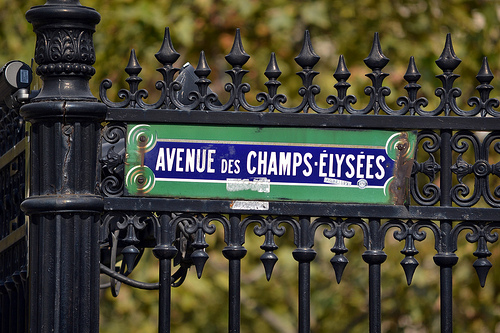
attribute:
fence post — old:
[18, 0, 108, 330]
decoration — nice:
[33, 25, 95, 79]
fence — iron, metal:
[2, 3, 499, 330]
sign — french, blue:
[147, 137, 397, 189]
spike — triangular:
[436, 37, 469, 80]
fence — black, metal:
[32, 37, 485, 272]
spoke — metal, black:
[435, 31, 457, 331]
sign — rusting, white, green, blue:
[129, 119, 420, 216]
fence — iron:
[16, 16, 487, 308]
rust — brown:
[393, 135, 415, 212]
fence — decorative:
[142, 13, 262, 328]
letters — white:
[154, 146, 385, 179]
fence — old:
[113, 29, 240, 329]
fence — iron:
[29, 35, 499, 309]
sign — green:
[79, 121, 415, 202]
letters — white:
[154, 142, 386, 182]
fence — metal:
[36, 219, 347, 319]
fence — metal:
[94, 215, 332, 295]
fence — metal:
[70, 227, 445, 312]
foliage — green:
[192, 18, 355, 62]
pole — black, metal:
[24, 211, 101, 328]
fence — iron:
[25, 29, 432, 323]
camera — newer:
[77, 110, 145, 190]